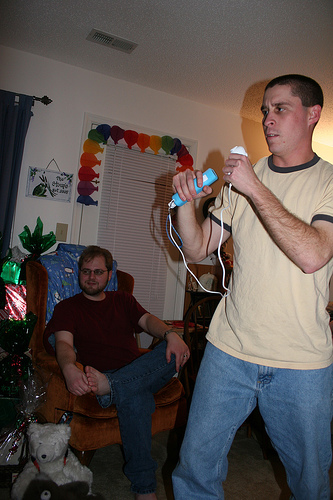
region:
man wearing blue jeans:
[200, 384, 217, 419]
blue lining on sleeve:
[312, 215, 330, 221]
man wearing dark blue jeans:
[133, 369, 148, 385]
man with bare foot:
[84, 369, 105, 392]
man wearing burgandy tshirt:
[93, 316, 112, 338]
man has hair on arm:
[61, 349, 68, 365]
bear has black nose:
[39, 452, 50, 461]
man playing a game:
[166, 73, 332, 498]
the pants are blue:
[170, 337, 332, 499]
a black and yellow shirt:
[205, 152, 332, 368]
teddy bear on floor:
[12, 424, 91, 495]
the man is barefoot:
[86, 366, 110, 395]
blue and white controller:
[168, 167, 215, 209]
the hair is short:
[265, 72, 323, 127]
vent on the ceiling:
[86, 26, 137, 54]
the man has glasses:
[80, 268, 110, 275]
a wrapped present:
[0, 263, 26, 319]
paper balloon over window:
[73, 186, 98, 206]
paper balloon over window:
[73, 176, 101, 192]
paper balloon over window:
[77, 163, 102, 183]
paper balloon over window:
[81, 153, 104, 172]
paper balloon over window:
[179, 153, 194, 167]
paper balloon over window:
[174, 139, 191, 161]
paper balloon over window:
[149, 133, 164, 159]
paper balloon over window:
[125, 128, 137, 147]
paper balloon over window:
[117, 125, 137, 149]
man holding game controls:
[142, 66, 331, 340]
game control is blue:
[164, 161, 214, 216]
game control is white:
[227, 143, 253, 170]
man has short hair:
[160, 66, 327, 303]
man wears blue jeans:
[163, 67, 330, 498]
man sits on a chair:
[38, 233, 190, 475]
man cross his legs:
[46, 239, 189, 492]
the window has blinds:
[87, 125, 188, 308]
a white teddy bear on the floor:
[5, 417, 95, 496]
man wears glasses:
[48, 239, 191, 412]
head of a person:
[247, 62, 324, 179]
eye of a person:
[244, 104, 296, 126]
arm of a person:
[234, 174, 321, 256]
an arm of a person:
[239, 182, 297, 257]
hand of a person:
[215, 155, 258, 190]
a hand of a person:
[210, 147, 268, 196]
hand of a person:
[163, 163, 222, 198]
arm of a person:
[169, 205, 224, 250]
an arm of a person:
[176, 202, 216, 248]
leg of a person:
[147, 354, 267, 460]